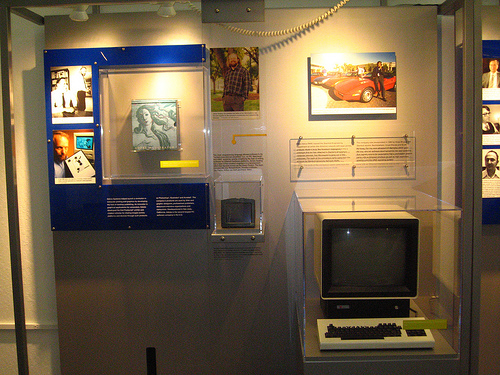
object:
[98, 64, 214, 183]
case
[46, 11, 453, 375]
wall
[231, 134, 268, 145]
cord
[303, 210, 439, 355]
computer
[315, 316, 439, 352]
keyboard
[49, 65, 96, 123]
picture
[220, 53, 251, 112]
man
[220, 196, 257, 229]
plate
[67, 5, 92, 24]
lights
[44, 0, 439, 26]
ceiling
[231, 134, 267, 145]
arrow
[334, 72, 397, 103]
car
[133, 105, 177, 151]
woman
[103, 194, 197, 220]
display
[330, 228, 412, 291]
monitor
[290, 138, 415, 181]
box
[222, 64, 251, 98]
shirt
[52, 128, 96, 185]
pictures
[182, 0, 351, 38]
cable